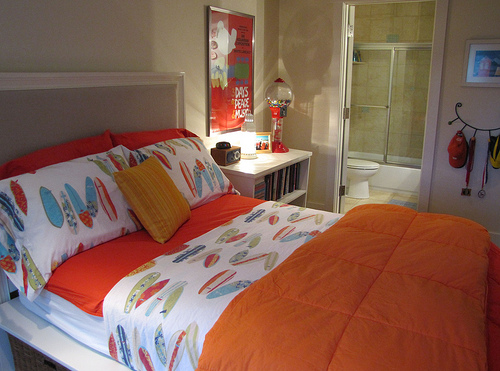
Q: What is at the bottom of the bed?
A: Orange blanket.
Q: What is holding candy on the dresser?
A: Gumball machine.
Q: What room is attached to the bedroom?
A: Bathroom.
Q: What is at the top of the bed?
A: Pillows.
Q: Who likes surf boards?
A: Owner of the room.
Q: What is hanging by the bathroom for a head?
A: Baseball cap.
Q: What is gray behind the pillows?
A: Headboard.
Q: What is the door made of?
A: Glass.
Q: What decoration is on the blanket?
A: Surfboards.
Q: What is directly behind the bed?
A: A gray headboard.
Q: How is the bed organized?
A: The bed is made.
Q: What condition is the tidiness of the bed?
A: Neat.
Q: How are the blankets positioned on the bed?
A: The blankets are neat.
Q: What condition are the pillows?
A: The pillows are organized.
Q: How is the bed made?
A: Neatly.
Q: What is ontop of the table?
A: A candy dispenser.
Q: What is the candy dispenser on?
A: A table.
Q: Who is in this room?
A: No one.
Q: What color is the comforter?
A: Orange.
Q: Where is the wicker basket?
A: Under the bed.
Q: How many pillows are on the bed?
A: 5.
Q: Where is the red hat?
A: On the wall.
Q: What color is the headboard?
A: Tan.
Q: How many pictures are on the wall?
A: 2.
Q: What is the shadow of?
A: The gumball machine.